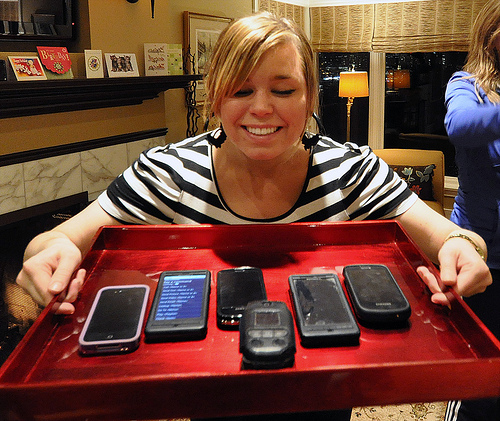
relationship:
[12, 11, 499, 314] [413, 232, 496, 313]
lady has hand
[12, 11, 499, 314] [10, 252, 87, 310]
lady has right hand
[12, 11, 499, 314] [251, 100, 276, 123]
lady has nose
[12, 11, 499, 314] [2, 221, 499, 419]
lady holding tray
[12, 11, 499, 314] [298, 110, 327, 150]
lady wearing earring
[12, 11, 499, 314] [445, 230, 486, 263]
lady wearing watch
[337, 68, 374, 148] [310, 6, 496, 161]
lamp beside window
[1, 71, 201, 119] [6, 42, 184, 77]
mantle has cards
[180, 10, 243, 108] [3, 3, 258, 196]
picture hanging on wall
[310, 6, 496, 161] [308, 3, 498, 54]
window has blinds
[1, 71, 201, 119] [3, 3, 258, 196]
mantle hanging on wall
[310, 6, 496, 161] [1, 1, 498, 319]
window inside room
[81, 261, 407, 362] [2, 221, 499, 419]
cell phones are on top of tray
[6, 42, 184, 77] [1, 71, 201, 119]
cards are along mantle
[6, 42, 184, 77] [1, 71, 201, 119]
cards are on top of mantle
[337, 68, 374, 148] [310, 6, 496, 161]
lamp in front of window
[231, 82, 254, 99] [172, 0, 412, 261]
eye of lady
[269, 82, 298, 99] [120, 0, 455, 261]
eye of lady